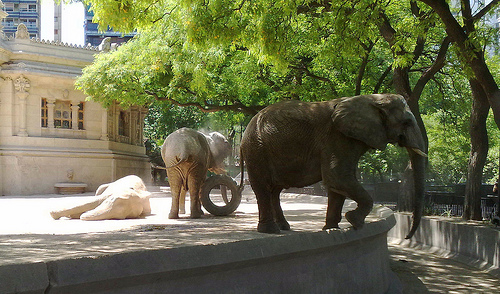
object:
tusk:
[413, 148, 428, 157]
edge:
[2, 207, 396, 294]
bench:
[54, 182, 87, 194]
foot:
[322, 222, 343, 235]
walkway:
[389, 244, 500, 293]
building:
[0, 24, 153, 198]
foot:
[344, 209, 365, 228]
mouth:
[392, 133, 406, 147]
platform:
[0, 216, 389, 293]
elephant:
[236, 93, 429, 239]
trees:
[73, 0, 498, 220]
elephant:
[48, 174, 150, 222]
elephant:
[149, 128, 232, 220]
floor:
[2, 186, 231, 246]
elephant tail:
[236, 145, 244, 195]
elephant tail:
[149, 153, 189, 170]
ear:
[331, 94, 388, 150]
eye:
[397, 116, 413, 125]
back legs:
[248, 174, 281, 234]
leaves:
[85, 2, 473, 164]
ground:
[0, 192, 499, 294]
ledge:
[5, 211, 403, 294]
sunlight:
[0, 195, 176, 235]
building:
[1, 0, 141, 46]